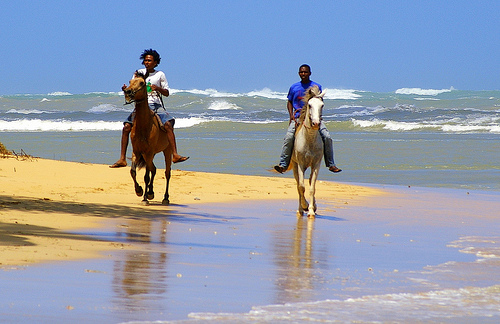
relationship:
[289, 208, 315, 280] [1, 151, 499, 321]
reflection in sand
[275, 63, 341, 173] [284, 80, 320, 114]
man in shirt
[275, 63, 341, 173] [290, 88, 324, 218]
man in horse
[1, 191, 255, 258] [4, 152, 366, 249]
shadows in sand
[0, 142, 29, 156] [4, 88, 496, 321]
vegetation in beach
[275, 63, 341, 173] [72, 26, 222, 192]
man in horse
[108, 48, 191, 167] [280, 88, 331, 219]
boy in horse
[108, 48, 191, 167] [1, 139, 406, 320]
boy in beach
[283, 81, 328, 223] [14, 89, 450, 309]
horse in beach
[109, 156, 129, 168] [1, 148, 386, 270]
foot in beach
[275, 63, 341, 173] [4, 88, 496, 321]
man in beach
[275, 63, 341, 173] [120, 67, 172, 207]
man in horse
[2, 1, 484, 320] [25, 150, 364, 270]
photograph taken on beach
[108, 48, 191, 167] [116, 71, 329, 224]
boy riding horses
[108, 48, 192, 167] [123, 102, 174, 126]
boy wearing jeans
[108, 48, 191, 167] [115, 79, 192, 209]
boy are riding horses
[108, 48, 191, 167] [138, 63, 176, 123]
boy wearing a shirt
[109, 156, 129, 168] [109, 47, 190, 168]
foot of person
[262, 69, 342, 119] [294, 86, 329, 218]
shirt riding horse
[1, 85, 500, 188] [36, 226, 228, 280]
ocean washing up on sand